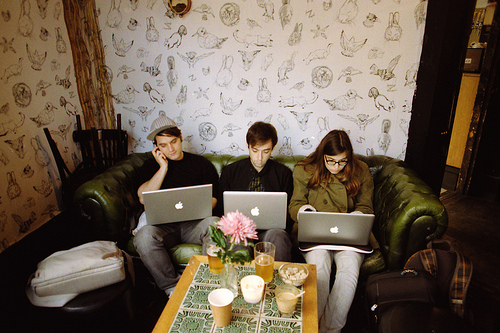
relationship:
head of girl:
[307, 127, 364, 187] [297, 122, 373, 332]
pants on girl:
[295, 238, 371, 331] [294, 120, 371, 324]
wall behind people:
[119, 47, 391, 102] [133, 113, 379, 238]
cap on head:
[144, 115, 177, 140] [139, 100, 191, 166]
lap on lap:
[295, 212, 371, 247] [285, 202, 372, 280]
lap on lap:
[295, 212, 371, 247] [290, 220, 372, 271]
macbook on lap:
[142, 178, 206, 219] [135, 210, 224, 252]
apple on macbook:
[173, 201, 186, 211] [142, 181, 215, 225]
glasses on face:
[325, 154, 346, 167] [321, 149, 347, 175]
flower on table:
[213, 209, 260, 244] [183, 245, 315, 331]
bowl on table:
[276, 263, 309, 283] [174, 249, 320, 331]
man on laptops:
[220, 118, 295, 253] [141, 178, 373, 240]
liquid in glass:
[251, 260, 276, 280] [255, 241, 276, 283]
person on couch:
[286, 124, 380, 305] [90, 142, 447, 301]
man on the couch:
[220, 118, 295, 253] [71, 142, 451, 285]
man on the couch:
[132, 109, 225, 289] [67, 155, 447, 296]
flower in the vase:
[205, 206, 264, 259] [220, 259, 255, 291]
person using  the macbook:
[286, 124, 380, 305] [295, 212, 376, 247]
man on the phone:
[124, 109, 225, 289] [148, 143, 167, 160]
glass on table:
[253, 238, 278, 287] [156, 252, 319, 327]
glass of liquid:
[253, 238, 278, 287] [257, 261, 269, 276]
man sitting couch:
[132, 109, 225, 289] [69, 143, 448, 313]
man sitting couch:
[220, 118, 295, 253] [69, 143, 448, 313]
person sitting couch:
[286, 124, 380, 305] [69, 143, 448, 313]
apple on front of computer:
[325, 221, 345, 240] [295, 200, 378, 244]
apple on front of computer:
[249, 200, 263, 217] [220, 189, 290, 233]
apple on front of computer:
[170, 201, 187, 211] [140, 179, 220, 230]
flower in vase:
[213, 209, 260, 244] [214, 259, 251, 287]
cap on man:
[144, 110, 177, 147] [132, 109, 225, 289]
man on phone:
[132, 109, 225, 289] [150, 146, 167, 162]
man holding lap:
[132, 109, 225, 289] [140, 181, 216, 225]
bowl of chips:
[276, 261, 314, 283] [282, 265, 303, 275]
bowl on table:
[276, 261, 314, 283] [148, 249, 328, 329]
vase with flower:
[207, 249, 280, 319] [184, 212, 264, 258]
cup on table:
[200, 271, 303, 328] [143, 232, 325, 328]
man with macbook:
[132, 109, 225, 289] [295, 212, 376, 247]